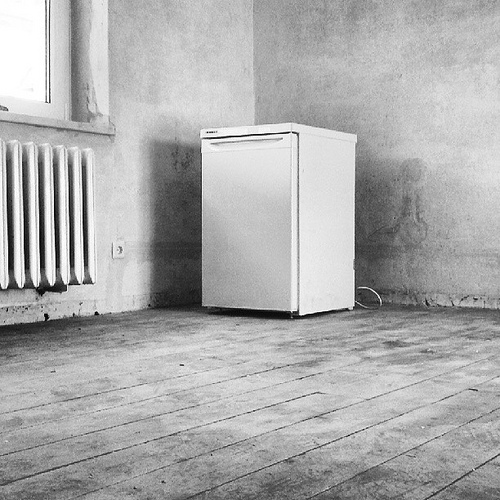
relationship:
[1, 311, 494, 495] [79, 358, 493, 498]
floor made of wood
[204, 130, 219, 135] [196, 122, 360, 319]
brand on fridge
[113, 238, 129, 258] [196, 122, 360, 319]
plug for device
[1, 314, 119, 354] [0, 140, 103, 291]
dirt below radiator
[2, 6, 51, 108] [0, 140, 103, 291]
window above radiator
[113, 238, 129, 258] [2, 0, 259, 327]
plug in wall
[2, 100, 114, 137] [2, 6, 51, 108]
sill below window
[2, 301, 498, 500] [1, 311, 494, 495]
more of floor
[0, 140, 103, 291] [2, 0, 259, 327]
radiator on wall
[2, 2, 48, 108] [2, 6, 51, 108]
light from window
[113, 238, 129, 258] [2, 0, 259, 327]
plug on wall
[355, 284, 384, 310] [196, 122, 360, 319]
cord of refrigerator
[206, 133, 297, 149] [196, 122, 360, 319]
handle of refrigerator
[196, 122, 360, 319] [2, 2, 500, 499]
refrigerator in room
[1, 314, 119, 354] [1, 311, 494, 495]
dirt on wood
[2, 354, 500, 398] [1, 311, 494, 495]
line on floor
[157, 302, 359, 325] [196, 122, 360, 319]
shadow under appliance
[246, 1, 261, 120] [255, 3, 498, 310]
edge of wall